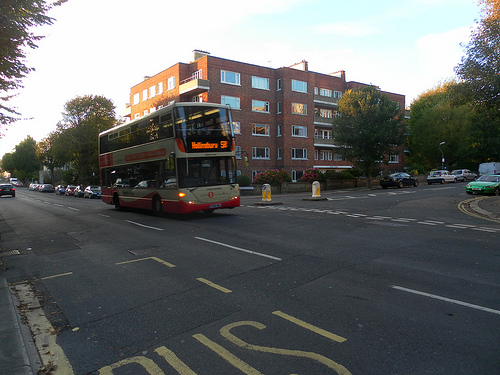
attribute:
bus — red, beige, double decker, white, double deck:
[98, 98, 249, 220]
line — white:
[188, 232, 283, 267]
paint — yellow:
[219, 327, 235, 335]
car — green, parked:
[456, 168, 498, 204]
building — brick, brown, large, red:
[122, 51, 406, 194]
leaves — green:
[436, 105, 450, 115]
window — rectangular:
[172, 105, 232, 141]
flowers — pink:
[253, 173, 269, 183]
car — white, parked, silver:
[423, 170, 456, 188]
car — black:
[375, 170, 422, 189]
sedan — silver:
[451, 165, 475, 181]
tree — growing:
[324, 79, 408, 201]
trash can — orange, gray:
[311, 180, 322, 199]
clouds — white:
[306, 16, 438, 77]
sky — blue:
[0, 4, 456, 134]